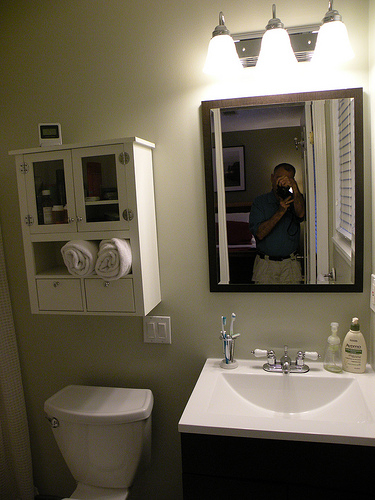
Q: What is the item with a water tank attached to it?
A: Toilet.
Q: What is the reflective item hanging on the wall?
A: Mirror.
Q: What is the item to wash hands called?
A: Sink.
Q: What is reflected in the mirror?
A: Man taking picture.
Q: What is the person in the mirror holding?
A: Camera.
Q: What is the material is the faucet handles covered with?
A: Ceramic.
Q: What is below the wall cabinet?
A: Toilet.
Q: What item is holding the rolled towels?
A: Wall cabinet.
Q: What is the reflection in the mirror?
A: Man holding camera.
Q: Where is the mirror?
A: On wall.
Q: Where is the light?
A: Above mirror.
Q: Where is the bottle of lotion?
A: On the right hand side of the sink.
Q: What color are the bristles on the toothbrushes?
A: Blue and white.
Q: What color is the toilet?
A: White.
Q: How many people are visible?
A: One.